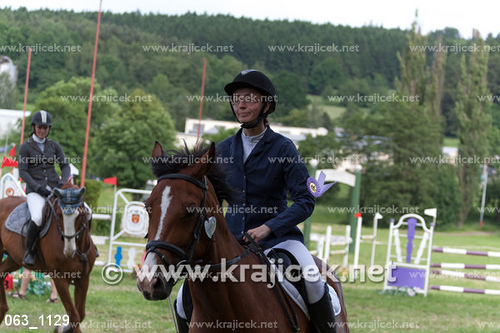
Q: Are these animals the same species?
A: Yes, all the animals are horses.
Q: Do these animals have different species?
A: No, all the animals are horses.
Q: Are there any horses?
A: Yes, there is a horse.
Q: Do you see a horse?
A: Yes, there is a horse.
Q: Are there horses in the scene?
A: Yes, there is a horse.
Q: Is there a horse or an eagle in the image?
A: Yes, there is a horse.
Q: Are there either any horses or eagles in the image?
A: Yes, there is a horse.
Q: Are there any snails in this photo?
A: No, there are no snails.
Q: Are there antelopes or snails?
A: No, there are no snails or antelopes.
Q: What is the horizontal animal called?
A: The animal is a horse.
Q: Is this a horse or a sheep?
A: This is a horse.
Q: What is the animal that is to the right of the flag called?
A: The animal is a horse.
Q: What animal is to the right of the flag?
A: The animal is a horse.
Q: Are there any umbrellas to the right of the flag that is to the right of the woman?
A: No, there is a horse to the right of the flag.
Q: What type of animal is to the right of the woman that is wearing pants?
A: The animal is a horse.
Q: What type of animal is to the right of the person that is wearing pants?
A: The animal is a horse.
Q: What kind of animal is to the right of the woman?
A: The animal is a horse.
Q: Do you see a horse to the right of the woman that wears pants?
A: Yes, there is a horse to the right of the woman.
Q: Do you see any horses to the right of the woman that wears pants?
A: Yes, there is a horse to the right of the woman.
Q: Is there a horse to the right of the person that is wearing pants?
A: Yes, there is a horse to the right of the woman.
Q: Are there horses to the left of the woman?
A: No, the horse is to the right of the woman.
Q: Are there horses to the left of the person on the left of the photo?
A: No, the horse is to the right of the woman.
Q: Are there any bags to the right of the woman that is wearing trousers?
A: No, there is a horse to the right of the woman.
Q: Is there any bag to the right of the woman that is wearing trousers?
A: No, there is a horse to the right of the woman.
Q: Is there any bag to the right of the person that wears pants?
A: No, there is a horse to the right of the woman.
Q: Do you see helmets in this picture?
A: Yes, there is a helmet.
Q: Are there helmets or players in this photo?
A: Yes, there is a helmet.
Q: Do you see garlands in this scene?
A: No, there are no garlands.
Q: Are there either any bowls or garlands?
A: No, there are no garlands or bowls.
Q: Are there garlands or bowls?
A: No, there are no garlands or bowls.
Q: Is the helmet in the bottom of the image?
A: No, the helmet is in the top of the image.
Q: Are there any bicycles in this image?
A: No, there are no bicycles.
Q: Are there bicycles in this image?
A: No, there are no bicycles.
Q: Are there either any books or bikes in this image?
A: No, there are no bikes or books.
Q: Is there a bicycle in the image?
A: No, there are no bicycles.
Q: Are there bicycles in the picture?
A: No, there are no bicycles.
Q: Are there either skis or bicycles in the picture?
A: No, there are no bicycles or skis.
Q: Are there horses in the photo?
A: Yes, there is a horse.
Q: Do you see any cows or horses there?
A: Yes, there is a horse.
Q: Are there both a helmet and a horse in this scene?
A: Yes, there are both a horse and a helmet.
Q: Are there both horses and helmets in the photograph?
A: Yes, there are both a horse and a helmet.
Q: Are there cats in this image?
A: No, there are no cats.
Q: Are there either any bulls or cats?
A: No, there are no cats or bulls.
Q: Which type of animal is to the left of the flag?
A: The animal is a horse.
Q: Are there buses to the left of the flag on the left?
A: No, there is a horse to the left of the flag.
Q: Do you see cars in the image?
A: No, there are no cars.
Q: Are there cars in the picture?
A: No, there are no cars.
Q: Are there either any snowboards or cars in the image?
A: No, there are no cars or snowboards.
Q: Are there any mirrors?
A: No, there are no mirrors.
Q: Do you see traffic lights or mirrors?
A: No, there are no mirrors or traffic lights.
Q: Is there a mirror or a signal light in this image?
A: No, there are no mirrors or traffic lights.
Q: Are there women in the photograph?
A: Yes, there is a woman.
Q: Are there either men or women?
A: Yes, there is a woman.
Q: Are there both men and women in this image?
A: No, there is a woman but no men.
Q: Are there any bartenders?
A: No, there are no bartenders.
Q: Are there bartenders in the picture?
A: No, there are no bartenders.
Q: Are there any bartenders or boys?
A: No, there are no bartenders or boys.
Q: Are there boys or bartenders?
A: No, there are no bartenders or boys.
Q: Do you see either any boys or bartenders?
A: No, there are no bartenders or boys.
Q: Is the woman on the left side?
A: Yes, the woman is on the left of the image.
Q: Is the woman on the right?
A: No, the woman is on the left of the image.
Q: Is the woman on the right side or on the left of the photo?
A: The woman is on the left of the image.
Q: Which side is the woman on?
A: The woman is on the left of the image.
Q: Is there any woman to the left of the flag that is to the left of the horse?
A: Yes, there is a woman to the left of the flag.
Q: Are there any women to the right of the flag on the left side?
A: No, the woman is to the left of the flag.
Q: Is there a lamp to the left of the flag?
A: No, there is a woman to the left of the flag.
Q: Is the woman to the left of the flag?
A: Yes, the woman is to the left of the flag.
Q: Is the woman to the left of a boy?
A: No, the woman is to the left of the flag.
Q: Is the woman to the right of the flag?
A: No, the woman is to the left of the flag.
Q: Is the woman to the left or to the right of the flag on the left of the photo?
A: The woman is to the left of the flag.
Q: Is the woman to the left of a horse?
A: Yes, the woman is to the left of a horse.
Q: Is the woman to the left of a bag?
A: No, the woman is to the left of a horse.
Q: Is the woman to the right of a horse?
A: No, the woman is to the left of a horse.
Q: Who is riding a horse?
A: The woman is riding a horse.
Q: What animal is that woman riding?
A: The woman is riding a horse.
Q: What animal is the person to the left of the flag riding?
A: The woman is riding a horse.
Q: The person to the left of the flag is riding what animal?
A: The woman is riding a horse.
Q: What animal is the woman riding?
A: The woman is riding a horse.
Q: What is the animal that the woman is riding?
A: The animal is a horse.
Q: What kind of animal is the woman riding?
A: The woman is riding a horse.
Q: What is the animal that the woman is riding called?
A: The animal is a horse.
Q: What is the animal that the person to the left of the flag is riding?
A: The animal is a horse.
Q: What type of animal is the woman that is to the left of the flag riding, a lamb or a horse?
A: The woman is riding a horse.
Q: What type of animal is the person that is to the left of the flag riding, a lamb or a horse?
A: The woman is riding a horse.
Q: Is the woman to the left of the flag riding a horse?
A: Yes, the woman is riding a horse.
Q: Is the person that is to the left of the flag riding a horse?
A: Yes, the woman is riding a horse.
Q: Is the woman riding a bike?
A: No, the woman is riding a horse.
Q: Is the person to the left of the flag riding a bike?
A: No, the woman is riding a horse.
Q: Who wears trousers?
A: The woman wears trousers.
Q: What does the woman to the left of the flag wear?
A: The woman wears pants.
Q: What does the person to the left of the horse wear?
A: The woman wears pants.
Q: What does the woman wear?
A: The woman wears pants.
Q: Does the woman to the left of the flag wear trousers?
A: Yes, the woman wears trousers.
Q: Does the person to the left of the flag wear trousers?
A: Yes, the woman wears trousers.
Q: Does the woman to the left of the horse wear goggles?
A: No, the woman wears trousers.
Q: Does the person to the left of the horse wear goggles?
A: No, the woman wears trousers.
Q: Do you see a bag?
A: No, there are no bags.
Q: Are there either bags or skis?
A: No, there are no bags or skis.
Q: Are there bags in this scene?
A: No, there are no bags.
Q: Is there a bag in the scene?
A: No, there are no bags.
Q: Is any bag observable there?
A: No, there are no bags.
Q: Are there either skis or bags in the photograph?
A: No, there are no bags or skis.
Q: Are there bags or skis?
A: No, there are no bags or skis.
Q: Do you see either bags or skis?
A: No, there are no bags or skis.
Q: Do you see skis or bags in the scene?
A: No, there are no bags or skis.